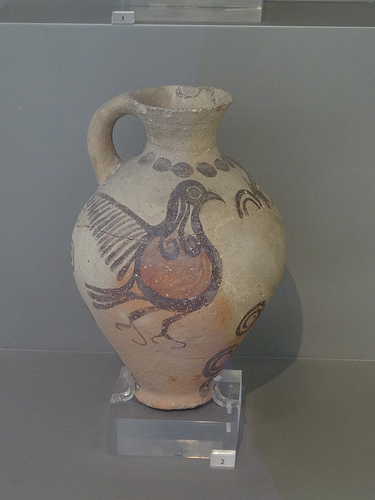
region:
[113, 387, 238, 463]
clear glass museum base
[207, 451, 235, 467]
the number 2 on a base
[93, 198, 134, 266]
black painted wing of a bird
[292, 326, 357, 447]
grey museum display area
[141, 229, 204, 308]
red painted belly of a bird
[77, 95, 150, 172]
handle of an antique clay pot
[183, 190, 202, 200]
eye of a painted bird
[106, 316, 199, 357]
feet of a painted bird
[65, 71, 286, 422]
antique clay pot in a display case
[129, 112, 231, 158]
neck of an antique clay pot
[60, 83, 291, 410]
brown old crock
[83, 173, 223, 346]
little bird on crock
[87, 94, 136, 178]
handle of crock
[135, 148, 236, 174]
black dots on crock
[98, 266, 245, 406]
orange part of crock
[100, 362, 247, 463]
transparent base in floor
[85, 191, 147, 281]
wings of bird on crock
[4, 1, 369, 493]
gray wall and gray floor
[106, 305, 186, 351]
two thin legs of bird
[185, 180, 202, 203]
little eye of bird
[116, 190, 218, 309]
A bird on the vase.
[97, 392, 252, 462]
The vase sitting on a glass platform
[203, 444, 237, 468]
The glass bottom has number 2 on it.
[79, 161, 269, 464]
The vase is sitting on table.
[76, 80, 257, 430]
Vase against the wall.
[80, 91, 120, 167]
The vas has handle.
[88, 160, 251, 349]
The vase is hand painted.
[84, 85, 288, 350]
The vase is made of ceramic.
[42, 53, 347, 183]
The wall is gray.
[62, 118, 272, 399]
The vase is on display.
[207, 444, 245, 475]
The number 2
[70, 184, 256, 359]
Bird on the vase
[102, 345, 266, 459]
Vase on glass base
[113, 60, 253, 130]
Top of base is circular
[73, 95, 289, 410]
Vase looks very old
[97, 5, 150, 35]
Number 1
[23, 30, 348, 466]
Vase sitting in display case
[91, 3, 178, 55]
Number one is above vase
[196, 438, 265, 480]
Number 2 is to the bottom right of the vase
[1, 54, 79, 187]
Background is gray and clear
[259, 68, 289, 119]
part of a wall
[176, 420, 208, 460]
part of a glass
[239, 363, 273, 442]
aprt fo a shade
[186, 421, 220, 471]
part of a glass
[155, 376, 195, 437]
aprt of a vaase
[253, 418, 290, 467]
aprt of a table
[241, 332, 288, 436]
aprt of a shade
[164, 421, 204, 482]
edgfe of a base